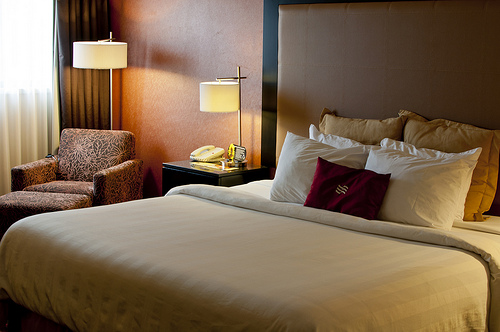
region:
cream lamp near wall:
[70, 39, 127, 71]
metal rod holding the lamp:
[107, 71, 114, 129]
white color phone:
[191, 144, 224, 162]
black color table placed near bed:
[162, 164, 232, 183]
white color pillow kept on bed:
[391, 152, 464, 223]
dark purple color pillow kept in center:
[313, 170, 373, 215]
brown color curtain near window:
[53, 3, 76, 129]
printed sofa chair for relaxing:
[51, 129, 141, 197]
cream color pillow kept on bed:
[323, 113, 497, 139]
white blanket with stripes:
[28, 217, 325, 312]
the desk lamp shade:
[195, 71, 244, 122]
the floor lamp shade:
[62, 37, 132, 75]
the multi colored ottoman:
[0, 190, 93, 236]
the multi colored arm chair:
[6, 124, 145, 200]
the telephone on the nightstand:
[187, 125, 227, 167]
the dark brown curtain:
[53, 3, 118, 130]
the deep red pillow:
[295, 152, 398, 234]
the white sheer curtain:
[2, 3, 59, 193]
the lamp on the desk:
[192, 51, 249, 166]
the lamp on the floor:
[64, 31, 138, 129]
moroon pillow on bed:
[309, 157, 385, 216]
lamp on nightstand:
[193, 66, 248, 168]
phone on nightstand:
[188, 141, 228, 167]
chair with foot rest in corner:
[4, 123, 140, 212]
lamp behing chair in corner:
[70, 29, 127, 126]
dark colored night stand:
[160, 161, 259, 193]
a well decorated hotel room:
[0, 15, 499, 328]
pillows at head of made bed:
[261, 106, 499, 228]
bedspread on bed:
[8, 230, 499, 304]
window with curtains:
[1, 2, 71, 132]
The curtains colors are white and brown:
[2, 0, 110, 195]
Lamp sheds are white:
[72, 40, 240, 112]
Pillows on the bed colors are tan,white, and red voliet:
[271, 108, 499, 230]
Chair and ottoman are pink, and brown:
[0, 125, 140, 225]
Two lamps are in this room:
[70, 30, 255, 165]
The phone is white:
[188, 141, 223, 161]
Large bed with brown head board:
[1, 0, 497, 330]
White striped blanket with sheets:
[0, 182, 497, 327]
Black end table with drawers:
[160, 158, 271, 193]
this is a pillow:
[316, 167, 368, 195]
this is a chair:
[46, 126, 128, 179]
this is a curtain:
[42, 42, 89, 101]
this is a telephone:
[191, 135, 226, 161]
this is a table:
[167, 156, 201, 176]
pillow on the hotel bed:
[302, 156, 390, 218]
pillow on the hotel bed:
[265, 131, 366, 203]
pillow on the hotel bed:
[363, 143, 460, 226]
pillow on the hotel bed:
[317, 106, 407, 146]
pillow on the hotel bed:
[300, 152, 390, 217]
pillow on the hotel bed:
[266, 128, 362, 204]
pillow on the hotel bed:
[361, 143, 466, 225]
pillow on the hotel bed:
[305, 123, 381, 153]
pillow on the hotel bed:
[378, 135, 478, 218]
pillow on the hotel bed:
[316, 105, 402, 142]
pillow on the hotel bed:
[300, 155, 392, 222]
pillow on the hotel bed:
[362, 143, 472, 228]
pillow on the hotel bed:
[267, 126, 367, 205]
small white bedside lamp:
[198, 72, 242, 162]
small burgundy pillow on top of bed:
[301, 159, 391, 220]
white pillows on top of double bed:
[268, 120, 480, 236]